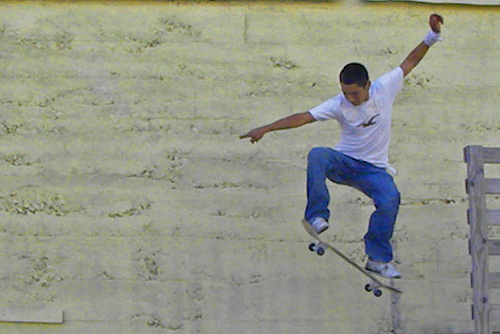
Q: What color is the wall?
A: Yellow.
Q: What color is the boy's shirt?
A: White.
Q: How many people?
A: One.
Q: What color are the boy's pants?
A: Blue.